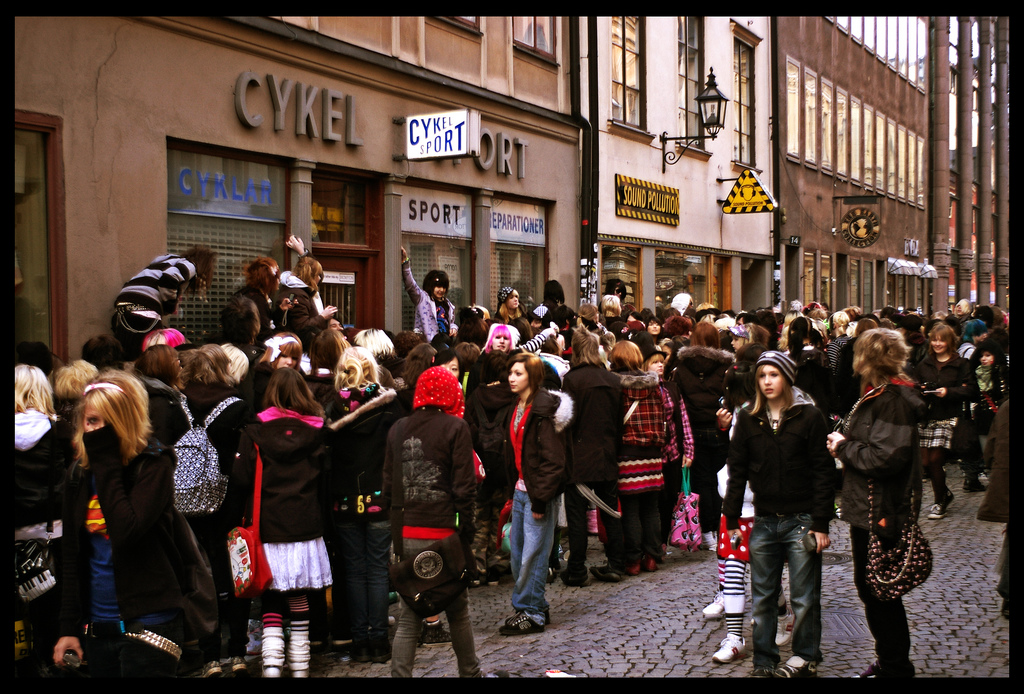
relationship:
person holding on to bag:
[217, 356, 339, 680] [181, 418, 307, 645]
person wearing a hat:
[717, 337, 841, 679] [749, 344, 823, 383]